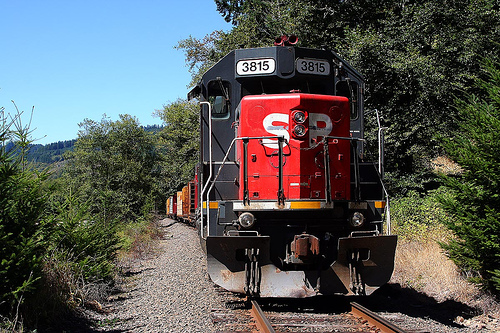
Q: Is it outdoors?
A: Yes, it is outdoors.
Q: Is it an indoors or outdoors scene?
A: It is outdoors.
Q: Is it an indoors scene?
A: No, it is outdoors.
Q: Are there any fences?
A: No, there are no fences.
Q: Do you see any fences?
A: No, there are no fences.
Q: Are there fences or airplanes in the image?
A: No, there are no fences or airplanes.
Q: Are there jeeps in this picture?
A: No, there are no jeeps.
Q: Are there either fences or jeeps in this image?
A: No, there are no jeeps or fences.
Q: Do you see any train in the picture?
A: Yes, there is a train.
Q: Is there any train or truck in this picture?
A: Yes, there is a train.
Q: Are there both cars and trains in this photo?
A: Yes, there are both a train and a car.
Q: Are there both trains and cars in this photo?
A: Yes, there are both a train and a car.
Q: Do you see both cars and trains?
A: Yes, there are both a train and a car.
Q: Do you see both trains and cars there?
A: Yes, there are both a train and a car.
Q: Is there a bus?
A: No, there are no buses.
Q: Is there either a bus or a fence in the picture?
A: No, there are no buses or fences.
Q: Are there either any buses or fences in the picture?
A: No, there are no buses or fences.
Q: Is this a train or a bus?
A: This is a train.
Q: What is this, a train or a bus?
A: This is a train.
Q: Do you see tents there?
A: No, there are no tents.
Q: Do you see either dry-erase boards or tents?
A: No, there are no tents or dry-erase boards.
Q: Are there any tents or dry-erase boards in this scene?
A: No, there are no tents or dry-erase boards.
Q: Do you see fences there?
A: No, there are no fences.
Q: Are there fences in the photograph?
A: No, there are no fences.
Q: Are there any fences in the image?
A: No, there are no fences.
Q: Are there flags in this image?
A: No, there are no flags.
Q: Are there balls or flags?
A: No, there are no flags or balls.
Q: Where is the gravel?
A: The gravel is on the railroad.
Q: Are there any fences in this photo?
A: No, there are no fences.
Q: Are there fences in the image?
A: No, there are no fences.